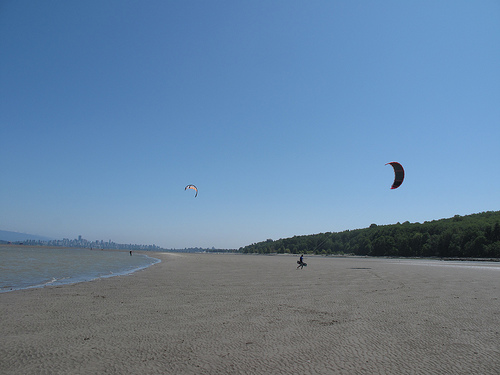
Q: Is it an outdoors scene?
A: Yes, it is outdoors.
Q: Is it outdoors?
A: Yes, it is outdoors.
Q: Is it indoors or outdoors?
A: It is outdoors.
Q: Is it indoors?
A: No, it is outdoors.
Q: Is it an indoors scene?
A: No, it is outdoors.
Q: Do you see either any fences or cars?
A: No, there are no fences or cars.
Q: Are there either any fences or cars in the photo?
A: No, there are no fences or cars.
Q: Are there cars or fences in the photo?
A: No, there are no fences or cars.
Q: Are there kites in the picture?
A: Yes, there is a kite.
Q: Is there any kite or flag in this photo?
A: Yes, there is a kite.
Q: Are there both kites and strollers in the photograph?
A: No, there is a kite but no strollers.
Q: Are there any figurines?
A: No, there are no figurines.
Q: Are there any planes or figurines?
A: No, there are no figurines or planes.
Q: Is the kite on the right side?
A: Yes, the kite is on the right of the image.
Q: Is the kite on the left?
A: No, the kite is on the right of the image.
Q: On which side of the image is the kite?
A: The kite is on the right of the image.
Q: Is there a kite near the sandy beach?
A: Yes, there is a kite near the beach.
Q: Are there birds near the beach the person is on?
A: No, there is a kite near the beach.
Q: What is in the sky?
A: The kite is in the sky.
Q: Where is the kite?
A: The kite is in the sky.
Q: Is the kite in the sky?
A: Yes, the kite is in the sky.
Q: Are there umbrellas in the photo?
A: No, there are no umbrellas.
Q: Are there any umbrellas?
A: No, there are no umbrellas.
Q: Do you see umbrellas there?
A: No, there are no umbrellas.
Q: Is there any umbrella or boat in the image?
A: No, there are no umbrellas or boats.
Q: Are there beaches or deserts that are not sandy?
A: No, there is a beach but it is sandy.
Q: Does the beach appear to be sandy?
A: Yes, the beach is sandy.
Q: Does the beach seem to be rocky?
A: No, the beach is sandy.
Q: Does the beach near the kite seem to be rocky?
A: No, the beach is sandy.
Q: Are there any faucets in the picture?
A: No, there are no faucets.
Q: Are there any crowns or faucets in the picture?
A: No, there are no faucets or crowns.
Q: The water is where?
A: The water is on the beach.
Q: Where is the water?
A: The water is on the beach.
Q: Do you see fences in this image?
A: No, there are no fences.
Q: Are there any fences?
A: No, there are no fences.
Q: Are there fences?
A: No, there are no fences.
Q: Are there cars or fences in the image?
A: No, there are no fences or cars.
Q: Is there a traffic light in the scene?
A: No, there are no traffic lights.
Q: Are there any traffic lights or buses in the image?
A: No, there are no traffic lights or buses.